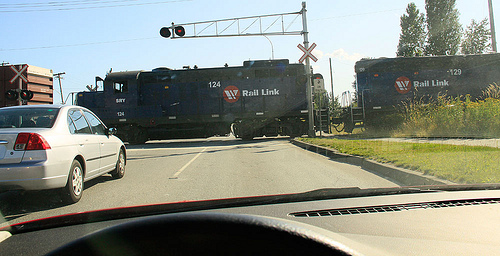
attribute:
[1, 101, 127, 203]
car — waiting, white, silver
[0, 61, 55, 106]
box car — red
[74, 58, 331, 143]
engine — black, blue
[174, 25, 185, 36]
light — red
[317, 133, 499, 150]
sidewalk — concrete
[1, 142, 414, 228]
street — asphalt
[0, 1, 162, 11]
powerline — above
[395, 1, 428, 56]
tree — behind, tall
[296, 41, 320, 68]
sign — red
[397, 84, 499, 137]
weeds — tall